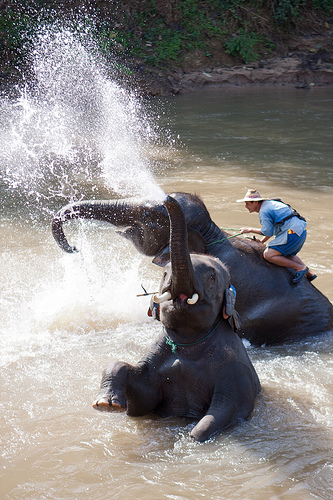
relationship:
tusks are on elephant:
[147, 290, 207, 305] [78, 193, 294, 457]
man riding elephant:
[236, 189, 317, 287] [50, 191, 332, 348]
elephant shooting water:
[92, 195, 262, 443] [1, 0, 195, 315]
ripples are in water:
[212, 160, 328, 191] [0, 83, 331, 498]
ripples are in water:
[25, 387, 330, 494] [0, 11, 325, 490]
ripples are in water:
[273, 389, 321, 424] [63, 75, 248, 196]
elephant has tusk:
[92, 195, 262, 443] [185, 291, 198, 305]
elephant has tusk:
[92, 195, 262, 443] [150, 287, 173, 304]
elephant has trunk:
[137, 194, 258, 429] [51, 197, 103, 252]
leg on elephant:
[92, 353, 152, 413] [92, 195, 262, 443]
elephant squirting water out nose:
[92, 195, 262, 443] [95, 194, 259, 450]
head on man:
[244, 199, 260, 211] [236, 189, 317, 287]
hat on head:
[233, 188, 268, 202] [244, 199, 260, 211]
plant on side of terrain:
[128, 11, 249, 52] [13, 10, 326, 277]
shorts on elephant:
[268, 224, 332, 265] [115, 192, 309, 351]